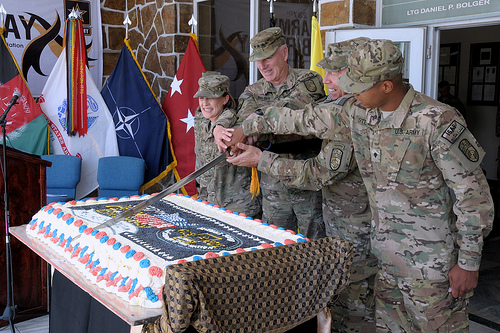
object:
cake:
[24, 192, 309, 307]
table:
[6, 224, 157, 324]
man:
[226, 38, 497, 332]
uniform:
[332, 82, 495, 304]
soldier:
[226, 37, 376, 333]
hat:
[247, 26, 289, 62]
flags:
[159, 38, 214, 197]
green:
[409, 143, 419, 149]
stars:
[168, 74, 184, 98]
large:
[55, 188, 301, 276]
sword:
[71, 152, 229, 242]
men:
[235, 25, 327, 240]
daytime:
[0, 0, 495, 281]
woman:
[193, 69, 236, 200]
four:
[193, 26, 441, 121]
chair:
[82, 155, 146, 201]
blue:
[140, 116, 160, 134]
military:
[118, 199, 227, 256]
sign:
[18, 10, 70, 83]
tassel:
[250, 166, 262, 200]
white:
[99, 252, 128, 268]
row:
[0, 7, 327, 151]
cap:
[337, 39, 405, 95]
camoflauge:
[372, 186, 449, 258]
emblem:
[106, 86, 151, 170]